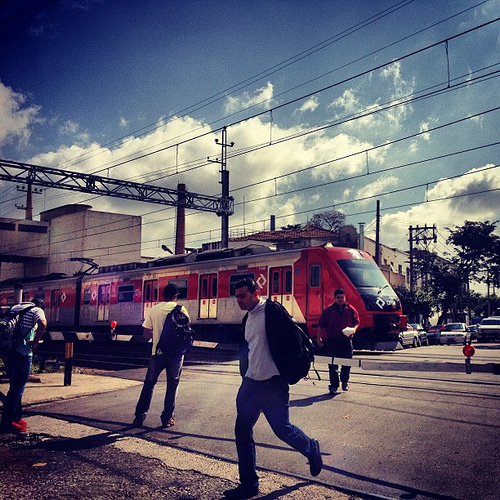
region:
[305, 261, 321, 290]
Small window on a red and silver tran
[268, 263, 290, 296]
Small window on a red and silver tran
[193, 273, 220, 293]
Small window on a red and silver tran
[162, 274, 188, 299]
Small window on a red and silver tran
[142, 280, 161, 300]
Small window on a red and silver tran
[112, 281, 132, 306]
Small window on a red and silver tran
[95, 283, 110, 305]
Small window on a red and silver tran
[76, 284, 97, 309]
Small window on a red and silver tran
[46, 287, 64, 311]
Small window on a red and silver tran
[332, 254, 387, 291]
Small window on a red and silver tran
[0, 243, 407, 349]
red and white train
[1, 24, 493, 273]
cables above the train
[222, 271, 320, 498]
man walking away from the train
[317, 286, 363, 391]
man standing by the train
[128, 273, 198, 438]
man with a back pack looking at the train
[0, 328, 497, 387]
baracade by the train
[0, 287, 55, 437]
man with a back pack waiting for the train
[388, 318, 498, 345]
cars parked in a parking lot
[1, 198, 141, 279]
building in the distance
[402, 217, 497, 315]
trees are behind the parking lot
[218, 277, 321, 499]
this is a man walking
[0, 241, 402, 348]
this is a train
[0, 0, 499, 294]
this is the sky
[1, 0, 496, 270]
these are power lines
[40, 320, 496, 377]
this is a gate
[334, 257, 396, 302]
this is a window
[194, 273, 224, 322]
this is a door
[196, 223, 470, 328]
this is a brick building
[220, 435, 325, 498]
these are his shoes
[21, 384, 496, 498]
this is the sidewalk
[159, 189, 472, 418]
a train on th tracks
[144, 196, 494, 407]
A train on train tracks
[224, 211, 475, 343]
a red train on teh track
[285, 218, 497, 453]
a red train on teh train track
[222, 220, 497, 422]
a passenger train on the tracks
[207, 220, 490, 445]
a passenger train on teh train track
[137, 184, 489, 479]
a red passenger train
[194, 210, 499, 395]
a track with a train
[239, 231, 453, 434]
a train track with at rain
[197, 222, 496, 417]
a track with a red train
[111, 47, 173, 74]
Part of the blue sky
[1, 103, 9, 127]
Part of the cloud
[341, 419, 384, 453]
Part of the ground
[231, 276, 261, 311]
The head of the person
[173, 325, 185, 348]
Part of the backpack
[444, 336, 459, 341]
Part of the car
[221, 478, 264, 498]
The right foot of the person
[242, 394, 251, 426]
Part of the pants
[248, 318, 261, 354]
Part of the shirt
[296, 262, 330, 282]
Part of the train